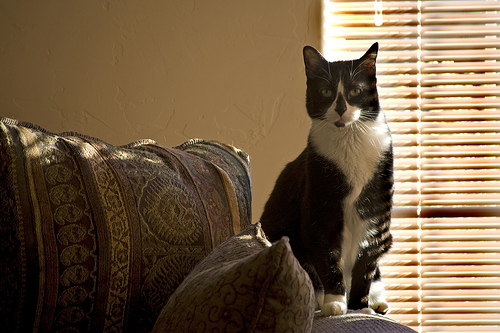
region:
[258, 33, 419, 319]
black and white cat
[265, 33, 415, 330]
cat sitting on the arm of the couch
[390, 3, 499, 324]
miniblinds covering a window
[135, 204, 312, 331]
throw pillow on the couch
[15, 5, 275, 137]
white plaster wall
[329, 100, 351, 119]
black nose of a cat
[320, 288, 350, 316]
white front paw of a cat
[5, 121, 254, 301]
multi colored couch fabric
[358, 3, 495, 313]
sunlight coming through closed blinds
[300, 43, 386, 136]
cat's head with black and white coloring on his fur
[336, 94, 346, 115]
black spot above the cat's black nose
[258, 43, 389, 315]
black and white cat on the couch's arm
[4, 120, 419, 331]
a couch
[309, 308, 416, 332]
arm of the couch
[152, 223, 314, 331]
pillow on the couch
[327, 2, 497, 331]
mini-blinds covering a window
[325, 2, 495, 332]
the window behind the cat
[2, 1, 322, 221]
the beige plaster wall to the left of the window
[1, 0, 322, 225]
the wall behind the couch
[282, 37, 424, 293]
cat is on arm of sofa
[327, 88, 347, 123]
cat has black patch on nose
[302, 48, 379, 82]
cat has black ears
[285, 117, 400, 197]
cat has white neck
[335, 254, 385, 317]
cat has black paws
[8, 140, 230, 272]
orange and burgundy pillow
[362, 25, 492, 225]
light brown shades on window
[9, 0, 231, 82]
tan wall near window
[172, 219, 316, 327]
pillow on sofa near cat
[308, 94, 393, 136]
cat has white whiskers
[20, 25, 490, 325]
The cat is in somebody's house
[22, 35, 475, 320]
The cat is in its master's home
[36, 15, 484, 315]
The cat is sitting on a couch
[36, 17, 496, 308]
The cat is waiting to be fed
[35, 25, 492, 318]
The cat just woke up from a nap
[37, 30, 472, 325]
The cat is awake in the daytime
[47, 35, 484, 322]
The cat has been hunting for mice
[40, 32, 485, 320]
The cat is waiting for its master's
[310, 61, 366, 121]
The face of a cat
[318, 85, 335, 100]
The eye of a cat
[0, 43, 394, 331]
The cat is sitting on a chair.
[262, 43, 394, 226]
The cat is black and white.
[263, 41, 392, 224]
The cat is looking at the camera.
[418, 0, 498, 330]
Blinds are on the window.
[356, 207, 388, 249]
Sunlight is on the cat.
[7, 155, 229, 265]
The chair is patterned.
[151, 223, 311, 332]
A pillow is on the chair.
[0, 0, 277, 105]
The wall is beige.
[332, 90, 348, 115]
The cat's nose is black.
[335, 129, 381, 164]
The cat's chest is white.